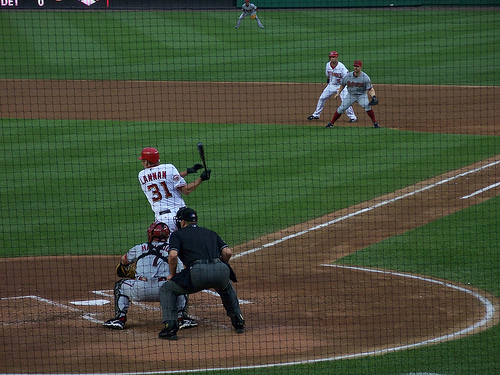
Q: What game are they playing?
A: Baseball.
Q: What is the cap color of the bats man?
A: Red.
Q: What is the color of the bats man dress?
A: White.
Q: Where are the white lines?
A: In the ground.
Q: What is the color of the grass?
A: Green.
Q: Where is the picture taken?
A: Baseball field.